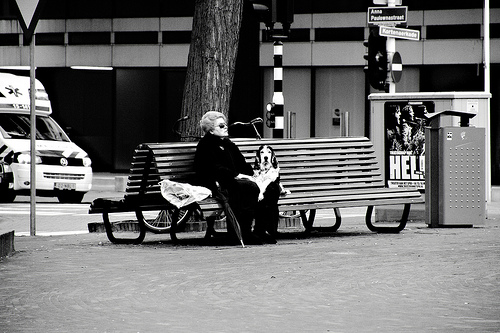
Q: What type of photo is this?
A: Black and white.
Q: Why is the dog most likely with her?
A: Blind.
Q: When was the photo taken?
A: Daytime.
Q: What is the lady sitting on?
A: Bench.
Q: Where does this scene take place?
A: Town.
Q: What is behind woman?
A: Ambulance.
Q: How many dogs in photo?
A: One.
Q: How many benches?
A: Two.